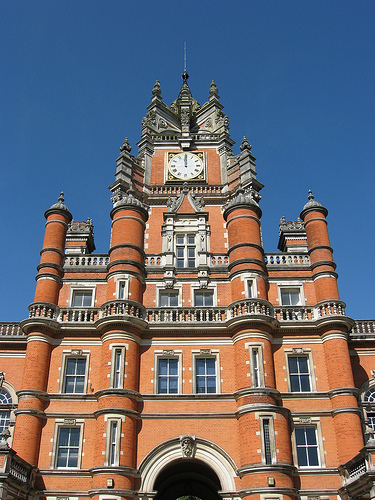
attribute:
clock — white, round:
[160, 147, 204, 189]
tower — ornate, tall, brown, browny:
[45, 37, 312, 498]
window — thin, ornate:
[149, 353, 181, 397]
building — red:
[54, 190, 374, 490]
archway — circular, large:
[139, 437, 243, 499]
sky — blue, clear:
[27, 9, 356, 81]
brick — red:
[208, 427, 219, 439]